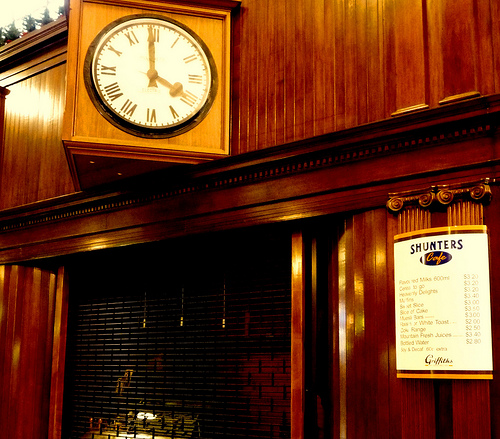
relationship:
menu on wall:
[386, 189, 499, 380] [226, 4, 497, 438]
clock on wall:
[74, 9, 243, 137] [226, 4, 497, 438]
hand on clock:
[144, 25, 168, 87] [74, 9, 243, 137]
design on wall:
[267, 135, 320, 180] [226, 4, 497, 438]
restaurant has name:
[10, 48, 500, 432] [405, 221, 486, 251]